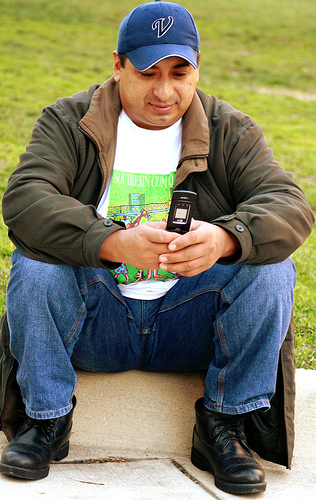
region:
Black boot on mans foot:
[189, 389, 272, 489]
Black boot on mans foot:
[0, 392, 81, 481]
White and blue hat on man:
[110, 1, 219, 68]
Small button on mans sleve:
[101, 212, 113, 232]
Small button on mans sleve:
[233, 220, 265, 243]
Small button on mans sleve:
[214, 211, 233, 218]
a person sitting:
[1, 0, 312, 498]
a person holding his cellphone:
[2, 0, 315, 498]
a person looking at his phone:
[2, 1, 314, 498]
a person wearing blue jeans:
[1, 1, 314, 498]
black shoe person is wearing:
[188, 396, 271, 496]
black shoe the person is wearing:
[0, 390, 77, 482]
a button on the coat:
[235, 222, 245, 233]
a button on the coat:
[103, 216, 113, 226]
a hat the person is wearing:
[114, 0, 203, 73]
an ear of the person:
[111, 48, 122, 82]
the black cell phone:
[166, 189, 197, 235]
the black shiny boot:
[191, 395, 266, 493]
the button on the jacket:
[1, 75, 314, 268]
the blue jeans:
[6, 247, 294, 418]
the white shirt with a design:
[95, 108, 180, 298]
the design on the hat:
[117, 0, 200, 72]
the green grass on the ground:
[0, 0, 315, 369]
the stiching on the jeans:
[6, 248, 295, 419]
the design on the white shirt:
[93, 108, 181, 299]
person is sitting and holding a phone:
[0, 0, 315, 495]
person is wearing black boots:
[0, 392, 266, 492]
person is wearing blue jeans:
[6, 245, 298, 420]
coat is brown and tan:
[0, 71, 315, 468]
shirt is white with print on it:
[96, 103, 185, 298]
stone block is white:
[56, 363, 207, 454]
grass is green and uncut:
[1, 0, 315, 372]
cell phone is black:
[167, 188, 196, 234]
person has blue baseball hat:
[117, 0, 200, 70]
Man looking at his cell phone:
[0, 0, 314, 494]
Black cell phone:
[165, 189, 196, 244]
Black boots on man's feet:
[0, 395, 267, 495]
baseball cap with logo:
[115, 1, 208, 80]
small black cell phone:
[167, 187, 194, 228]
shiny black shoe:
[190, 398, 269, 492]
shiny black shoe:
[0, 416, 75, 477]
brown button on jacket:
[234, 222, 244, 233]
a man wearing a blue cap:
[9, 4, 314, 494]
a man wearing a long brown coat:
[5, 3, 304, 497]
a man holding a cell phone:
[6, 6, 311, 493]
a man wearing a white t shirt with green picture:
[9, 15, 308, 498]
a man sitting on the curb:
[8, 9, 314, 494]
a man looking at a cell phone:
[3, 1, 300, 495]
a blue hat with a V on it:
[107, 1, 203, 75]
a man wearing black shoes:
[9, 6, 306, 497]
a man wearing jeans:
[9, 4, 307, 493]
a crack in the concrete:
[69, 453, 231, 498]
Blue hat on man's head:
[106, 0, 206, 132]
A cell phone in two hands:
[114, 179, 227, 281]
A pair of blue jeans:
[0, 240, 298, 420]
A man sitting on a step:
[0, 0, 310, 493]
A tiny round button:
[228, 217, 248, 234]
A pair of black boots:
[0, 391, 270, 493]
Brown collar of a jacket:
[73, 68, 216, 172]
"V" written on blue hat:
[141, 4, 182, 40]